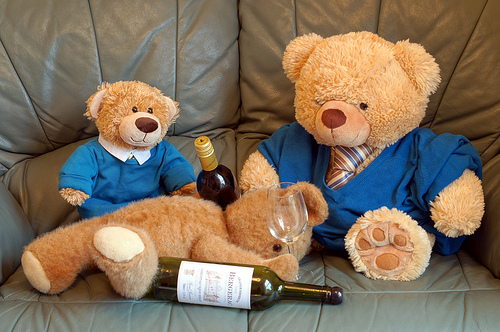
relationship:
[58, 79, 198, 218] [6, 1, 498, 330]
bear on couch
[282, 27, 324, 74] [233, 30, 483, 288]
ear on a bear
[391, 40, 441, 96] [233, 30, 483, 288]
ear on a bear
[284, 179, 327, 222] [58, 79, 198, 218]
ear on a bear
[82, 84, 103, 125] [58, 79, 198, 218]
ear on a bear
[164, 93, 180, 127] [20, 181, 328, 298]
ear on a bear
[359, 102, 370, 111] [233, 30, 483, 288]
eye on bear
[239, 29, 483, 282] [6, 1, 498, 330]
bear on couch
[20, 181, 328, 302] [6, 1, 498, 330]
bear on couch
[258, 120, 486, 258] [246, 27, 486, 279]
shirt on teddy bear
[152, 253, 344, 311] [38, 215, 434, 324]
bottle on cushion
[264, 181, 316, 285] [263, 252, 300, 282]
glass on hand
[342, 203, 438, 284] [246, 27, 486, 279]
paw on teddy bear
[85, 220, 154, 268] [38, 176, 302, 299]
paw on bear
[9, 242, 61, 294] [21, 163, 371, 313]
paw on bear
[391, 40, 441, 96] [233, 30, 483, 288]
ear of bear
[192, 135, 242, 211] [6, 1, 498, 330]
bottle on couch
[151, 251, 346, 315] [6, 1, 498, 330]
bottle on couch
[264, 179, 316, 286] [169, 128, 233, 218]
glass in hand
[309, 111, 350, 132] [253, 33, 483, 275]
nose on bear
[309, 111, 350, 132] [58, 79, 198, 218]
nose on bear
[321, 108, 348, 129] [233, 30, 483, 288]
nose on bear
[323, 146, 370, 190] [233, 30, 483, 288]
tie on bear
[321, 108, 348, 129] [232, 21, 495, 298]
nose on bear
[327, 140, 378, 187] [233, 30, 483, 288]
tie on bear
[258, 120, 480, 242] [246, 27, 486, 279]
shirt on teddy bear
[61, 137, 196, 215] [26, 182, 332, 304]
shirt on teddy bear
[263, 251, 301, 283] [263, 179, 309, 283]
hand holding glass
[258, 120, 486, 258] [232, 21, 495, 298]
shirt on bear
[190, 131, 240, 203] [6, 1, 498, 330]
bottle on couch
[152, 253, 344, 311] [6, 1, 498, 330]
bottle on couch